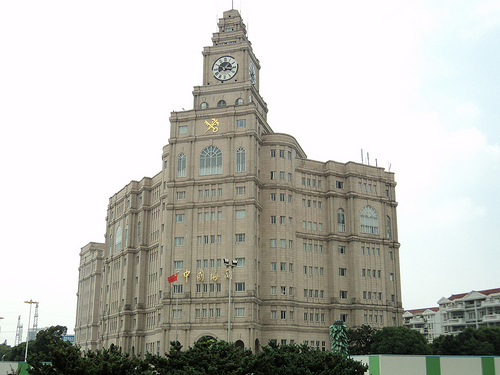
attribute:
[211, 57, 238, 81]
clock — white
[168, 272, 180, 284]
flag — flying, red, China  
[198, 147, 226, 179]
window — arched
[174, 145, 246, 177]
windows — many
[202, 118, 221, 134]
logo — golden, gold, key , health 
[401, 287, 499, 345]
apartment building — residential 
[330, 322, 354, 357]
tree — green, large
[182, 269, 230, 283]
emblems — golden, yellow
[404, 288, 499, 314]
roof — red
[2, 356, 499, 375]
wall — multi-colored, striped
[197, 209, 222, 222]
windows — plentiful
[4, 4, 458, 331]
sky — white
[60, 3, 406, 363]
building — tan, tall, large, showing, beige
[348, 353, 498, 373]
wall — green, white